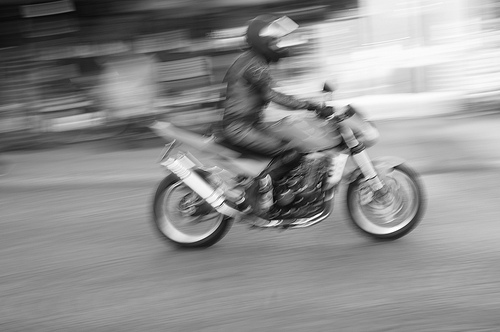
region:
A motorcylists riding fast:
[138, 8, 428, 255]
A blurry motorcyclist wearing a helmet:
[230, 11, 307, 221]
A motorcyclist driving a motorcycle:
[220, 10, 304, 222]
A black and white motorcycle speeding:
[152, 81, 424, 256]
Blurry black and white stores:
[3, 1, 498, 144]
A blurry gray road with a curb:
[6, 153, 492, 330]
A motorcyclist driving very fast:
[224, 13, 310, 220]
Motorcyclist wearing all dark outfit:
[222, 12, 327, 225]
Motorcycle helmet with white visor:
[247, 8, 307, 61]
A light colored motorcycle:
[151, 115, 431, 242]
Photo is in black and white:
[15, 7, 480, 328]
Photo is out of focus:
[19, 9, 477, 314]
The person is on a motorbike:
[139, 11, 429, 261]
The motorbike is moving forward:
[131, 21, 445, 257]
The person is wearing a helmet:
[230, 10, 322, 77]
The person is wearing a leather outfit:
[217, 43, 327, 200]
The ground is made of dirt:
[13, 247, 485, 326]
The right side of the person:
[220, 13, 328, 227]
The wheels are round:
[148, 166, 438, 248]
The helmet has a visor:
[267, 14, 300, 38]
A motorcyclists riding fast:
[141, 11, 432, 256]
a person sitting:
[213, 15, 322, 224]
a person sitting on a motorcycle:
[143, 11, 425, 251]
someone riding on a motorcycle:
[138, 11, 435, 251]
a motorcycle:
[133, 88, 431, 252]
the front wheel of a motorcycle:
[342, 157, 428, 244]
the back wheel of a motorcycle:
[146, 171, 236, 255]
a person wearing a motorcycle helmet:
[241, 13, 311, 63]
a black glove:
[301, 97, 330, 116]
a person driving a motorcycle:
[131, 13, 435, 264]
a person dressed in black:
[217, 13, 309, 226]